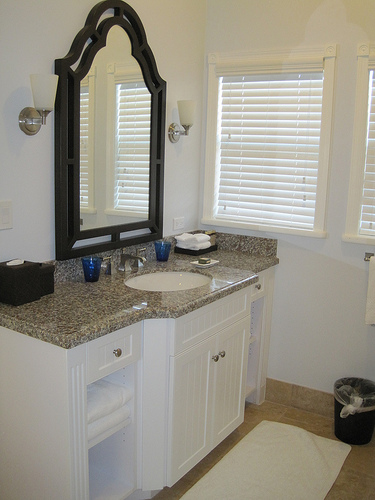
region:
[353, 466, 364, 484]
part of a floor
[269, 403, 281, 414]
par of a line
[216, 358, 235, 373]
part of a handle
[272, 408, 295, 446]
edge of a mat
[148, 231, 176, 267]
The glass is blue.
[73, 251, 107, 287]
The glass is blue.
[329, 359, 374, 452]
The trash can has a liner in it.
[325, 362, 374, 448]
The trash can is dark brown.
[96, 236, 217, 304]
The sink basin is white.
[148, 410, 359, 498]
The floor mat is white.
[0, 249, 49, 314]
The tissue holder is dark brown.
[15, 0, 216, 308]
The mirror is hanging above the sink.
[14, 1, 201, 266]
Lights hang on each side of the mirror.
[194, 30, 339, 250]
The window has a white mini blind.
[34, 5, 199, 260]
mirror hanging on wall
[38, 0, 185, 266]
mirror has dark brown trim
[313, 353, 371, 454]
wastebasket on floor near wall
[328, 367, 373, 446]
wastebasket has clear bag inside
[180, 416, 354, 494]
white rug on floor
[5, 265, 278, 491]
bathroom cabinets are white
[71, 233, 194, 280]
two blue glasses on counter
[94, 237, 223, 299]
bathroom sink is white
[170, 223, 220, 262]
towels folded on counter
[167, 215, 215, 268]
folded towels are white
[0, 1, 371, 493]
Interior view, daytime, with natural light.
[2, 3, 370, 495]
Interior of home, depicting bathroom.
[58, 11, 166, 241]
Wall-mounted mirror, with decorative, brown frame.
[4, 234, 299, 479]
Marble-topped, bathroom vanity.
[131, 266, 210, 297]
White sink bowl.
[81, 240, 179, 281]
Modern fixtures, with blue glasses, on either side.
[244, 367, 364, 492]
Wood floor, with white rug and garbage receptacle and liner.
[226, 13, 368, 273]
White walls, with windows and horizontal blinds.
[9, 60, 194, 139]
Set of silver sconses with white light fixtures.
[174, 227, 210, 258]
Folded, white towels, between marble corner and mirror.